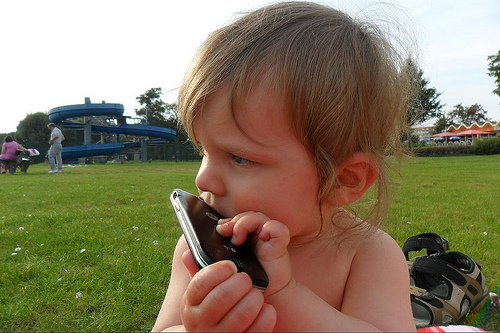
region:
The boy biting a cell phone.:
[161, 0, 411, 332]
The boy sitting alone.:
[156, 0, 413, 332]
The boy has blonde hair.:
[155, 2, 430, 331]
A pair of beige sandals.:
[406, 229, 496, 329]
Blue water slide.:
[46, 94, 179, 164]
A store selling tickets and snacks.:
[424, 105, 496, 150]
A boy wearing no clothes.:
[141, 0, 416, 331]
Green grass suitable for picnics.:
[4, 172, 166, 329]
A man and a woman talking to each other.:
[0, 118, 75, 175]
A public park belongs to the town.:
[1, 0, 496, 332]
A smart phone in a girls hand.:
[153, 188, 278, 300]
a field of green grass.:
[0, 152, 498, 331]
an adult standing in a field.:
[38, 115, 72, 176]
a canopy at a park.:
[401, 115, 497, 160]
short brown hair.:
[161, 0, 431, 254]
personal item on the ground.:
[379, 214, 498, 329]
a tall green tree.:
[392, 53, 447, 123]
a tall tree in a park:
[130, 77, 187, 134]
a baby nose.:
[186, 140, 231, 200]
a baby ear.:
[297, 137, 389, 247]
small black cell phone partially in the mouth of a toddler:
[170, 187, 270, 289]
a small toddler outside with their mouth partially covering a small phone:
[151, 1, 418, 331]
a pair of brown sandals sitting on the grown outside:
[404, 232, 485, 327]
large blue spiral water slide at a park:
[47, 95, 177, 166]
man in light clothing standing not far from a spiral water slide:
[46, 120, 64, 170]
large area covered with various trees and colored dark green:
[1, 86, 207, 160]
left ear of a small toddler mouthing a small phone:
[325, 152, 383, 209]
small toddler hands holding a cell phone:
[181, 210, 289, 332]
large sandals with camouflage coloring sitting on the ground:
[403, 230, 489, 328]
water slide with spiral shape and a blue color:
[47, 95, 177, 165]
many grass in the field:
[3, 242, 140, 327]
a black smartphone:
[170, 189, 267, 284]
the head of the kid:
[197, 1, 399, 239]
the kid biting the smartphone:
[171, 0, 416, 332]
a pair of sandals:
[406, 235, 481, 327]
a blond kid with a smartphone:
[162, 4, 419, 331]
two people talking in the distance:
[3, 125, 68, 174]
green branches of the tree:
[136, 90, 175, 125]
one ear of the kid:
[332, 149, 375, 207]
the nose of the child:
[196, 156, 226, 201]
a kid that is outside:
[99, 15, 477, 332]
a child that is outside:
[139, 2, 495, 312]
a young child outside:
[104, 29, 431, 328]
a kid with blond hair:
[91, 23, 453, 263]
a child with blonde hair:
[148, 1, 497, 167]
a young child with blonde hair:
[160, 6, 492, 311]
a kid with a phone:
[144, 1, 469, 331]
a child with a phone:
[152, 23, 460, 329]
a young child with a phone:
[140, 33, 450, 330]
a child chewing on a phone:
[105, 41, 428, 330]